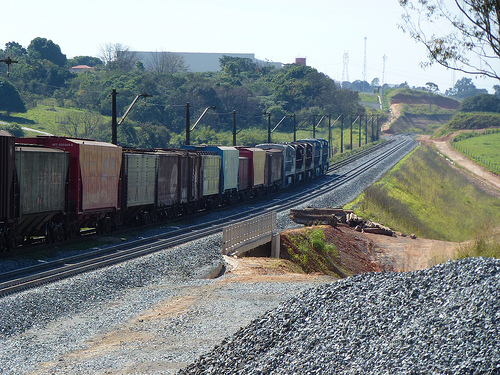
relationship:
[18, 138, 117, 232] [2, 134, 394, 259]
freight car riding on track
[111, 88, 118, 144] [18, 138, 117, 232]
pole behind freight car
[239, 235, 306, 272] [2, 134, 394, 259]
culvert under track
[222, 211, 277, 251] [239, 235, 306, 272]
bridge above culvert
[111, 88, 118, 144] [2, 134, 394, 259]
pole alongside track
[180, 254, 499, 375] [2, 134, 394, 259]
pile near track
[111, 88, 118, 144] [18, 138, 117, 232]
pole next to freight car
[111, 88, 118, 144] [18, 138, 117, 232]
pole near freight car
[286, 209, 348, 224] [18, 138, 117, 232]
logs are near freight car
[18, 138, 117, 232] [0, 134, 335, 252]
freight car part of freight car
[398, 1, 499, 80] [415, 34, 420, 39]
tree has leaf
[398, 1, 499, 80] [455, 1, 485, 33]
tree has branch